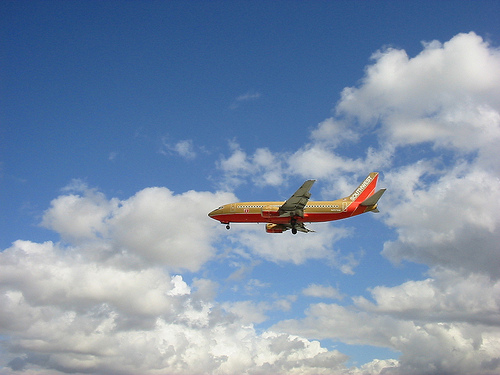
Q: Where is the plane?
A: In the sky.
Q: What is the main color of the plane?
A: Gold and red.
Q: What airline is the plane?
A: South West.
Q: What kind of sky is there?
A: Cloudy.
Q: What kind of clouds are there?
A: Fluffy ones.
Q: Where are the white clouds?
A: In the sky.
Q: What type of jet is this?
A: Passenger.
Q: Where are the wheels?
A: Down.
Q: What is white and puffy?
A: Clouds.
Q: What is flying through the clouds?
A: Plane.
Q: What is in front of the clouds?
A: Plane.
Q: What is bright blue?
A: Sky.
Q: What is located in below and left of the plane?
A: Clouds.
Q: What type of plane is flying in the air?
A: Jet plane.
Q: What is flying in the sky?
A: Plane.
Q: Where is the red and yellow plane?
A: In the sky.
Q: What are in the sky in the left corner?
A: Fluffy white clouds.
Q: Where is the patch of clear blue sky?
A: Upper left corner.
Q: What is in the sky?
A: Airplane.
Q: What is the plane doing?
A: Flying.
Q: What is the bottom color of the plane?
A: Red.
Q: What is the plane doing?
A: Landing.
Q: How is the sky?
A: Blue with clouds.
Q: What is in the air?
A: A plane.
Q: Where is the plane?
A: In the sky.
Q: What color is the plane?
A: Brown and red.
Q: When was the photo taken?
A: Daytime.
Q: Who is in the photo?
A: No one.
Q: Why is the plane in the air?
A: It is flying.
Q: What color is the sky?
A: Blue.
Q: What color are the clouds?
A: White.